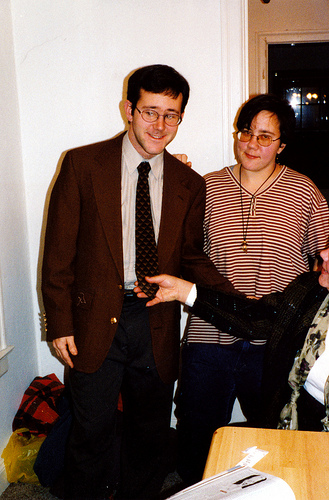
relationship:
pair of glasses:
[127, 106, 183, 129] [122, 93, 188, 139]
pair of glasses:
[127, 97, 187, 138] [127, 87, 186, 133]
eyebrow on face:
[139, 104, 161, 109] [137, 96, 180, 156]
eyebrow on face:
[164, 106, 181, 116] [137, 96, 180, 156]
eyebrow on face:
[237, 127, 254, 132] [234, 116, 274, 173]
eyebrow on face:
[257, 129, 277, 137] [234, 121, 276, 169]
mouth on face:
[142, 129, 170, 144] [136, 98, 182, 159]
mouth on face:
[240, 150, 264, 164] [234, 116, 274, 173]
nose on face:
[154, 113, 166, 134] [137, 96, 180, 156]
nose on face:
[245, 141, 264, 152] [234, 116, 274, 173]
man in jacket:
[39, 60, 265, 497] [39, 128, 246, 388]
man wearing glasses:
[39, 60, 265, 497] [134, 103, 182, 128]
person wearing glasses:
[172, 96, 327, 484] [231, 129, 281, 151]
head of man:
[121, 62, 191, 161] [39, 60, 265, 497]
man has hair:
[39, 60, 258, 497] [124, 62, 190, 114]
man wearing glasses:
[39, 60, 258, 497] [132, 102, 184, 127]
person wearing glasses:
[172, 96, 327, 484] [234, 128, 281, 147]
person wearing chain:
[172, 96, 327, 484] [236, 162, 277, 254]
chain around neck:
[236, 162, 277, 254] [240, 155, 278, 185]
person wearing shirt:
[172, 96, 327, 484] [176, 165, 318, 350]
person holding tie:
[129, 244, 318, 430] [136, 159, 161, 300]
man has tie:
[39, 60, 258, 497] [136, 159, 161, 300]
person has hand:
[172, 96, 327, 484] [170, 152, 193, 170]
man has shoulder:
[39, 60, 258, 497] [168, 154, 211, 209]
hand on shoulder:
[170, 152, 193, 170] [168, 154, 211, 209]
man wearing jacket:
[39, 60, 258, 497] [34, 128, 249, 387]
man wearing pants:
[39, 60, 258, 497] [61, 290, 169, 498]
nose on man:
[153, 108, 165, 133] [39, 60, 258, 497]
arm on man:
[39, 153, 80, 371] [39, 60, 258, 497]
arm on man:
[179, 176, 261, 301] [39, 60, 258, 497]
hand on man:
[46, 333, 83, 368] [39, 60, 258, 497]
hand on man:
[240, 291, 267, 300] [39, 60, 258, 497]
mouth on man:
[147, 133, 168, 145] [39, 60, 258, 497]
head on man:
[121, 62, 191, 155] [39, 60, 258, 497]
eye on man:
[146, 109, 157, 116] [39, 60, 258, 497]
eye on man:
[162, 111, 175, 118] [39, 60, 258, 497]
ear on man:
[118, 96, 137, 126] [39, 60, 258, 497]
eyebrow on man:
[139, 104, 161, 109] [39, 60, 258, 497]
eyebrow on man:
[164, 107, 180, 117] [39, 60, 258, 497]